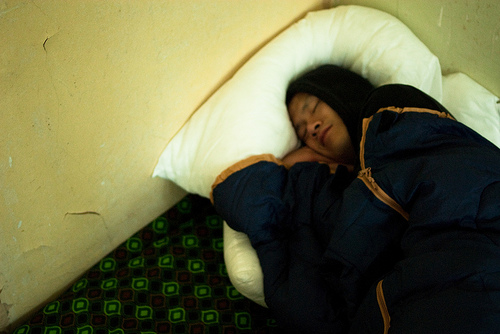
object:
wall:
[0, 1, 329, 334]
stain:
[7, 154, 15, 166]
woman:
[212, 66, 499, 334]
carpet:
[0, 193, 277, 333]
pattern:
[153, 215, 168, 233]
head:
[286, 62, 376, 161]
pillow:
[152, 6, 443, 200]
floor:
[0, 193, 499, 333]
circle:
[155, 220, 164, 230]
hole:
[65, 206, 105, 223]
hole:
[42, 32, 56, 54]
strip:
[210, 153, 287, 232]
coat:
[212, 86, 499, 331]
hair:
[285, 65, 376, 151]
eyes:
[300, 102, 320, 118]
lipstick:
[319, 124, 333, 145]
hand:
[286, 146, 335, 167]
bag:
[210, 106, 500, 333]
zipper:
[357, 167, 384, 197]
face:
[286, 93, 351, 159]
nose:
[307, 119, 323, 137]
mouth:
[319, 124, 334, 147]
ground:
[2, 194, 500, 333]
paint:
[234, 184, 255, 236]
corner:
[311, 2, 368, 70]